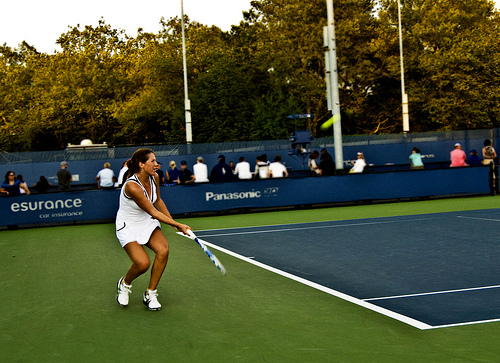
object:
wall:
[347, 132, 499, 169]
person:
[253, 156, 270, 179]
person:
[408, 148, 426, 171]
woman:
[117, 147, 192, 312]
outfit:
[115, 173, 163, 248]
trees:
[0, 0, 496, 141]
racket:
[183, 228, 227, 277]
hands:
[145, 201, 193, 237]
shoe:
[116, 275, 133, 309]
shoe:
[142, 288, 161, 311]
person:
[1, 170, 32, 198]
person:
[56, 161, 73, 191]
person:
[95, 162, 116, 190]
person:
[166, 160, 181, 183]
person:
[177, 159, 195, 186]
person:
[232, 156, 253, 181]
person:
[266, 155, 289, 179]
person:
[318, 152, 336, 177]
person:
[347, 151, 367, 174]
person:
[449, 142, 470, 167]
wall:
[287, 179, 358, 202]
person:
[114, 147, 192, 312]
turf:
[0, 206, 500, 363]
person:
[193, 156, 210, 183]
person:
[210, 155, 234, 184]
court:
[1, 191, 500, 363]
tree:
[0, 40, 59, 146]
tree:
[58, 13, 137, 144]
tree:
[114, 13, 226, 143]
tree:
[238, 0, 392, 137]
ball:
[321, 113, 341, 130]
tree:
[141, 12, 206, 143]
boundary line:
[178, 230, 429, 330]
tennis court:
[174, 202, 500, 331]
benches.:
[212, 147, 335, 184]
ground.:
[2, 194, 499, 363]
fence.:
[369, 166, 491, 201]